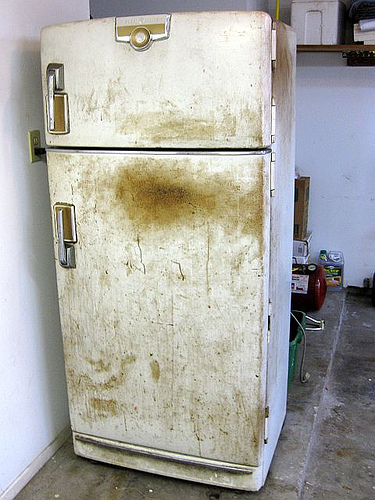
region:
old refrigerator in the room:
[38, 14, 290, 494]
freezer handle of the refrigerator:
[39, 63, 68, 139]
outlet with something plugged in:
[26, 127, 43, 164]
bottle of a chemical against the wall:
[316, 247, 346, 294]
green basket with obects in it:
[282, 306, 310, 381]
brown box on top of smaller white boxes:
[293, 169, 312, 244]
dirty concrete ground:
[0, 277, 373, 496]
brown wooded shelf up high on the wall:
[294, 44, 373, 53]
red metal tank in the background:
[291, 259, 329, 312]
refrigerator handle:
[53, 197, 76, 268]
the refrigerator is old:
[30, 0, 306, 490]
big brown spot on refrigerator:
[106, 158, 251, 237]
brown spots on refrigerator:
[38, 11, 283, 495]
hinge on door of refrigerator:
[264, 24, 281, 63]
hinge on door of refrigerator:
[268, 92, 277, 149]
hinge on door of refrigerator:
[262, 296, 274, 345]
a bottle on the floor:
[313, 246, 347, 299]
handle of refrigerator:
[42, 67, 58, 132]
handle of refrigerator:
[48, 207, 72, 267]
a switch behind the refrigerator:
[24, 122, 44, 164]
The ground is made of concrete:
[307, 342, 371, 497]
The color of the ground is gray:
[314, 346, 374, 487]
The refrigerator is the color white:
[23, 2, 314, 496]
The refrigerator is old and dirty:
[100, 118, 238, 422]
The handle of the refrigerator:
[53, 198, 83, 271]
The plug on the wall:
[26, 126, 46, 165]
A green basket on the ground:
[283, 308, 318, 393]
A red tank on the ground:
[289, 253, 330, 316]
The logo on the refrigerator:
[112, 11, 176, 52]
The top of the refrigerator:
[39, 11, 283, 149]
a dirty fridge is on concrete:
[39, 12, 288, 489]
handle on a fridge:
[57, 207, 69, 265]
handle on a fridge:
[46, 61, 63, 132]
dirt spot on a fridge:
[114, 163, 223, 224]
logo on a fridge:
[114, 15, 176, 50]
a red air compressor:
[291, 260, 324, 316]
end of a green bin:
[289, 311, 304, 382]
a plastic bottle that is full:
[318, 248, 345, 293]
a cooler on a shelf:
[290, 2, 345, 45]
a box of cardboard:
[295, 174, 310, 238]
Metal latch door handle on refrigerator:
[55, 207, 74, 268]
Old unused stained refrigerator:
[34, 10, 294, 492]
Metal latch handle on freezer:
[42, 62, 64, 134]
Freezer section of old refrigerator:
[25, 9, 298, 150]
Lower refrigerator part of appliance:
[39, 146, 292, 492]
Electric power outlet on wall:
[27, 129, 44, 161]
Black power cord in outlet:
[34, 144, 47, 158]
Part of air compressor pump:
[293, 258, 328, 312]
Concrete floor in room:
[10, 284, 369, 498]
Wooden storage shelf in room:
[297, 43, 374, 53]